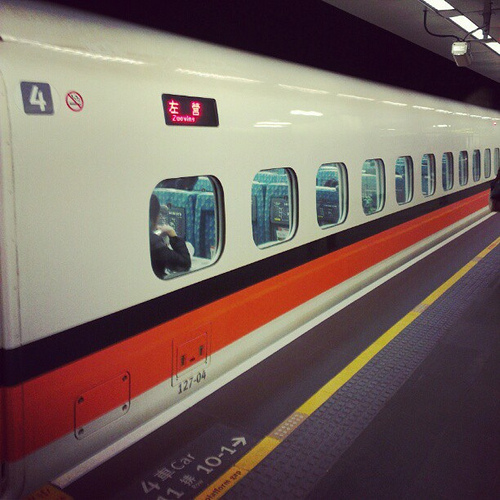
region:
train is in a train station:
[5, 6, 499, 488]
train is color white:
[1, 7, 499, 483]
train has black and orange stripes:
[0, 229, 368, 342]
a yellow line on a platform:
[302, 295, 497, 477]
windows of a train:
[149, 133, 496, 297]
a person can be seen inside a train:
[146, 172, 229, 277]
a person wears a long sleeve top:
[144, 175, 229, 282]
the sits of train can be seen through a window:
[243, 163, 303, 248]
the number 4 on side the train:
[10, 58, 67, 129]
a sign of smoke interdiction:
[58, 83, 88, 115]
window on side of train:
[154, 185, 222, 265]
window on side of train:
[242, 163, 294, 242]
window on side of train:
[317, 162, 337, 222]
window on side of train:
[363, 160, 388, 214]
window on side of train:
[383, 155, 415, 205]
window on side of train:
[413, 155, 434, 191]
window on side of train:
[453, 153, 473, 190]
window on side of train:
[473, 150, 480, 181]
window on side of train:
[470, 145, 488, 173]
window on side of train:
[492, 149, 498, 172]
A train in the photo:
[60, 137, 154, 216]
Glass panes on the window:
[255, 180, 293, 240]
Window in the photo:
[137, 182, 237, 273]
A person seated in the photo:
[147, 200, 196, 284]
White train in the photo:
[248, 89, 412, 156]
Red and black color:
[169, 254, 341, 321]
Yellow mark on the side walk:
[276, 390, 355, 430]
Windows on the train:
[137, 154, 384, 251]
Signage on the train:
[149, 86, 219, 124]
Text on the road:
[137, 427, 252, 497]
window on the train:
[155, 172, 237, 244]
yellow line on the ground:
[281, 334, 392, 432]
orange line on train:
[188, 278, 263, 348]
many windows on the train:
[117, 140, 477, 295]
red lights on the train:
[135, 78, 238, 149]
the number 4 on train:
[22, 75, 68, 120]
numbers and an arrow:
[189, 425, 256, 488]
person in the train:
[122, 190, 198, 267]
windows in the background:
[450, 140, 499, 188]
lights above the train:
[424, 3, 470, 43]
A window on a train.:
[142, 170, 238, 288]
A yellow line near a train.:
[198, 228, 498, 498]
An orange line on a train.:
[0, 185, 494, 472]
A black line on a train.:
[0, 170, 499, 394]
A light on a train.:
[156, 91, 225, 130]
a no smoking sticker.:
[60, 83, 96, 120]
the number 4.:
[15, 77, 57, 122]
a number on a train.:
[169, 358, 219, 408]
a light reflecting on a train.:
[166, 64, 263, 97]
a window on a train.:
[250, 155, 307, 255]